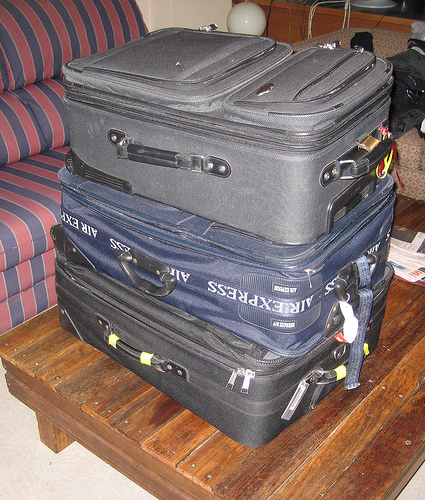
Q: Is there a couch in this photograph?
A: Yes, there is a couch.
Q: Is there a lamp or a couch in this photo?
A: Yes, there is a couch.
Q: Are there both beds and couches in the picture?
A: No, there is a couch but no beds.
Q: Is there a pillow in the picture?
A: No, there are no pillows.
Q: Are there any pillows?
A: No, there are no pillows.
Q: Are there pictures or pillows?
A: No, there are no pillows or pictures.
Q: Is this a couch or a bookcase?
A: This is a couch.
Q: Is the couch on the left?
A: Yes, the couch is on the left of the image.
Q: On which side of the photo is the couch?
A: The couch is on the left of the image.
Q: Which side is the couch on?
A: The couch is on the left of the image.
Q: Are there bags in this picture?
A: Yes, there is a bag.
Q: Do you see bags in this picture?
A: Yes, there is a bag.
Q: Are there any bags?
A: Yes, there is a bag.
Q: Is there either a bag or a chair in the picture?
A: Yes, there is a bag.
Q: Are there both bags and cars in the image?
A: No, there is a bag but no cars.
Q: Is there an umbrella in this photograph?
A: No, there are no umbrellas.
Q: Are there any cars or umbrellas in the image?
A: No, there are no umbrellas or cars.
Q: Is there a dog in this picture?
A: No, there are no dogs.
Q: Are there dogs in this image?
A: No, there are no dogs.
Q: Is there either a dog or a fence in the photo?
A: No, there are no dogs or fences.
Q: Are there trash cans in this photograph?
A: No, there are no trash cans.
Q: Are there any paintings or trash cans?
A: No, there are no trash cans or paintings.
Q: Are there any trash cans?
A: No, there are no trash cans.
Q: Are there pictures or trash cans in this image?
A: No, there are no trash cans or pictures.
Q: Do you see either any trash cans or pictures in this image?
A: No, there are no trash cans or pictures.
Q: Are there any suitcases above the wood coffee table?
A: Yes, there is a suitcase above the coffee table.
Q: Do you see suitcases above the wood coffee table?
A: Yes, there is a suitcase above the coffee table.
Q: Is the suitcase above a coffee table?
A: Yes, the suitcase is above a coffee table.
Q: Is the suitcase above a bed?
A: No, the suitcase is above a coffee table.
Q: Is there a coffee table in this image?
A: Yes, there is a coffee table.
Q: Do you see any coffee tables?
A: Yes, there is a coffee table.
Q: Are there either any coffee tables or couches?
A: Yes, there is a coffee table.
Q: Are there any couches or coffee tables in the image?
A: Yes, there is a coffee table.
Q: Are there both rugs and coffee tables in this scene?
A: No, there is a coffee table but no rugs.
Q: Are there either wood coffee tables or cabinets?
A: Yes, there is a wood coffee table.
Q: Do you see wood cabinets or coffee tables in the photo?
A: Yes, there is a wood coffee table.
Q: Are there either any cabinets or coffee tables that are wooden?
A: Yes, the coffee table is wooden.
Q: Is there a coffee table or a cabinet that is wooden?
A: Yes, the coffee table is wooden.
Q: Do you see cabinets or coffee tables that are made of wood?
A: Yes, the coffee table is made of wood.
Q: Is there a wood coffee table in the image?
A: Yes, there is a wood coffee table.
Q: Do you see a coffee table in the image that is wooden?
A: Yes, there is a wood coffee table.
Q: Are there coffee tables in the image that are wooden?
A: Yes, there is a coffee table that is wooden.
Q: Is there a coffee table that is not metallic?
A: Yes, there is a wooden coffee table.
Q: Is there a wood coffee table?
A: Yes, there is a coffee table that is made of wood.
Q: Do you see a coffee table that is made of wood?
A: Yes, there is a coffee table that is made of wood.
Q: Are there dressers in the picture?
A: No, there are no dressers.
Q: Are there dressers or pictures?
A: No, there are no dressers or pictures.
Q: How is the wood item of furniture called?
A: The piece of furniture is a coffee table.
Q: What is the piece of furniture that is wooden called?
A: The piece of furniture is a coffee table.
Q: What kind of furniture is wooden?
A: The furniture is a coffee table.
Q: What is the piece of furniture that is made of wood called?
A: The piece of furniture is a coffee table.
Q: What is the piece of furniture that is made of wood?
A: The piece of furniture is a coffee table.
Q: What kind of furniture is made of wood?
A: The furniture is a coffee table.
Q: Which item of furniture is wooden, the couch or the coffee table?
A: The coffee table is wooden.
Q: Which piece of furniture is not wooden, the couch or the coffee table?
A: The couch is not wooden.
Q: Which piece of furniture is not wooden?
A: The piece of furniture is a couch.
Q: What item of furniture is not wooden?
A: The piece of furniture is a couch.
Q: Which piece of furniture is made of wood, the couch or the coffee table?
A: The coffee table is made of wood.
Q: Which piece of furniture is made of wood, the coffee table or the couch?
A: The coffee table is made of wood.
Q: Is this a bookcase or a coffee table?
A: This is a coffee table.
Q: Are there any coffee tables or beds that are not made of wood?
A: No, there is a coffee table but it is made of wood.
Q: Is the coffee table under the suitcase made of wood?
A: Yes, the coffee table is made of wood.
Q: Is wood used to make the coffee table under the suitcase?
A: Yes, the coffee table is made of wood.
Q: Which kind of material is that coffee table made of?
A: The coffee table is made of wood.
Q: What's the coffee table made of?
A: The coffee table is made of wood.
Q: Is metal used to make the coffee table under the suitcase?
A: No, the coffee table is made of wood.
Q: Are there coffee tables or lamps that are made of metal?
A: No, there is a coffee table but it is made of wood.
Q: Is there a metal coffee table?
A: No, there is a coffee table but it is made of wood.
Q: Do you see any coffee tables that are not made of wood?
A: No, there is a coffee table but it is made of wood.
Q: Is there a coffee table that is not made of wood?
A: No, there is a coffee table but it is made of wood.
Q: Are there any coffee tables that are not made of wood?
A: No, there is a coffee table but it is made of wood.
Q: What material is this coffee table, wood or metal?
A: The coffee table is made of wood.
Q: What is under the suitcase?
A: The coffee table is under the suitcase.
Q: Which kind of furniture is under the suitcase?
A: The piece of furniture is a coffee table.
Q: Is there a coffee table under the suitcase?
A: Yes, there is a coffee table under the suitcase.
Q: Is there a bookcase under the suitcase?
A: No, there is a coffee table under the suitcase.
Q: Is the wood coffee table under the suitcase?
A: Yes, the coffee table is under the suitcase.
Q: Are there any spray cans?
A: No, there are no spray cans.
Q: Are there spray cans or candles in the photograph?
A: No, there are no spray cans or candles.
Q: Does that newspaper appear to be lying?
A: Yes, the newspaper is lying.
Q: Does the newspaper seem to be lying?
A: Yes, the newspaper is lying.